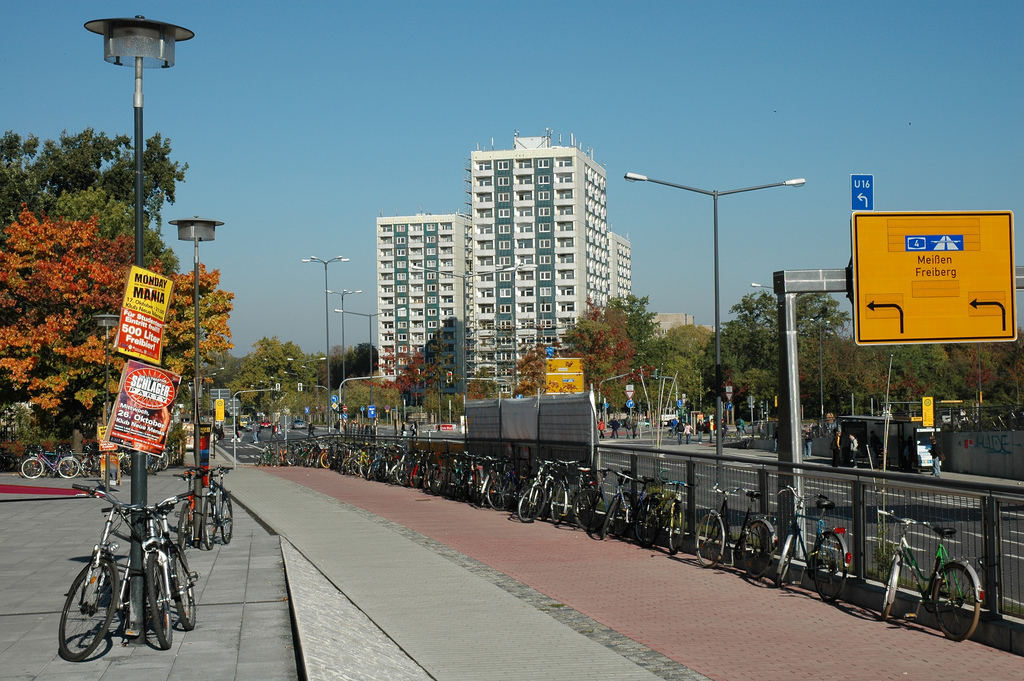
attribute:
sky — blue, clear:
[0, 8, 1021, 385]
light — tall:
[610, 165, 808, 369]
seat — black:
[100, 502, 145, 521]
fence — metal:
[266, 433, 1007, 633]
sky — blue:
[5, 2, 1020, 353]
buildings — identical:
[365, 145, 635, 390]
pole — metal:
[93, 67, 163, 634]